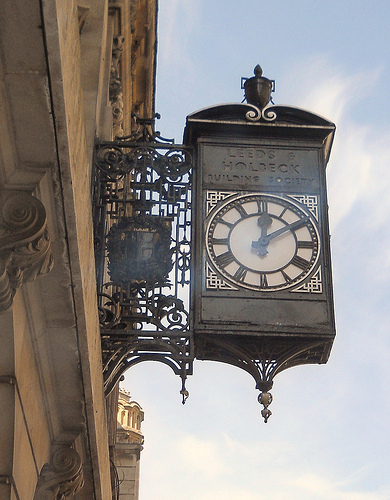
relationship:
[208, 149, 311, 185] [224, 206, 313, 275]
words are on clock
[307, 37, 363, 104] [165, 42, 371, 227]
clouds are in sky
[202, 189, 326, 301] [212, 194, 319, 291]
clock has face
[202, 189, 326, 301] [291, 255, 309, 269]
clock has number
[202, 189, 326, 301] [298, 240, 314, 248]
clock has number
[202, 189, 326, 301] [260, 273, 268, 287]
clock has numerals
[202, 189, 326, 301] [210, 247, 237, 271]
clock has roman numeral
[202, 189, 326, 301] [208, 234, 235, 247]
clock has roman numeral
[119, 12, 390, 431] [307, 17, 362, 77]
clouds in sky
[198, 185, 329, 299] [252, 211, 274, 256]
clock has black hands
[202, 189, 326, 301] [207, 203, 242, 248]
clock has black numbers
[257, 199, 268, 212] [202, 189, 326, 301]
black numbers on clock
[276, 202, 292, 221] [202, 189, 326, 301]
number on clock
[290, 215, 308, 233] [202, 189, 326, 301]
number on clock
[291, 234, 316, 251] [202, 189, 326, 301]
number on clock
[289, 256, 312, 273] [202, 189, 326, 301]
number on clock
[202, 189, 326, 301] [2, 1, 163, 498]
clock on building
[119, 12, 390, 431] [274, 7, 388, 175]
clouds in sky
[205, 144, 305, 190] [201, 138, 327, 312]
words above clock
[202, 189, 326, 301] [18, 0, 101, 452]
clock near building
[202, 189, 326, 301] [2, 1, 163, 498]
clock near building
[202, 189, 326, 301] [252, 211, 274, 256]
clock has black hands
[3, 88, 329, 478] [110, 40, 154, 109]
building has window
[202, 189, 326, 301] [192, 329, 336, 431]
clock has bottom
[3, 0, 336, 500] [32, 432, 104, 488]
building has design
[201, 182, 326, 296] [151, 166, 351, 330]
design around clock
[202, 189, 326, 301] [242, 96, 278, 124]
clock has design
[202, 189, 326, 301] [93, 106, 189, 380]
clock on iron bracket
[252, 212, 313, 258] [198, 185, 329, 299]
black hands on clock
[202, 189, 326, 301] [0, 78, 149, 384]
clock on side of building